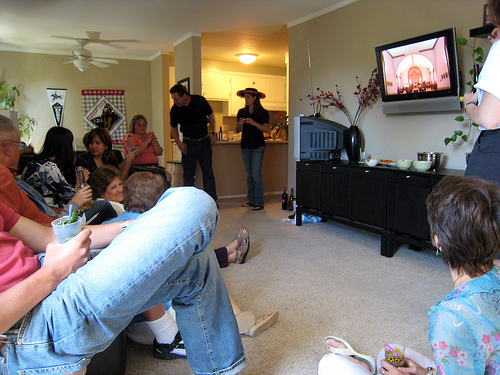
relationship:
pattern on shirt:
[438, 294, 484, 363] [418, 262, 497, 370]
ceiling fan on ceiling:
[42, 37, 119, 71] [2, 4, 159, 54]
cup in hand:
[55, 207, 89, 264] [42, 226, 91, 279]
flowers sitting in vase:
[298, 67, 384, 124] [342, 124, 362, 164]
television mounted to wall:
[373, 25, 467, 120] [283, 5, 499, 242]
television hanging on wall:
[373, 27, 466, 115] [287, 18, 367, 90]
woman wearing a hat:
[232, 87, 280, 210] [229, 82, 271, 106]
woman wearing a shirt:
[232, 87, 280, 210] [220, 103, 287, 148]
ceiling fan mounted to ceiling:
[42, 37, 119, 71] [44, 42, 120, 77]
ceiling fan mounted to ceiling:
[48, 44, 114, 72] [1, 1, 298, 29]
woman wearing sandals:
[69, 117, 129, 192] [233, 223, 251, 264]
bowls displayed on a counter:
[394, 152, 450, 189] [287, 125, 499, 274]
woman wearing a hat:
[232, 87, 280, 210] [232, 86, 266, 100]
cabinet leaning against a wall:
[295, 159, 429, 255] [287, 26, 372, 80]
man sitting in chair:
[0, 115, 63, 237] [89, 341, 126, 372]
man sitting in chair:
[2, 183, 248, 373] [89, 341, 126, 372]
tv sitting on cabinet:
[293, 113, 351, 165] [295, 159, 429, 255]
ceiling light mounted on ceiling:
[223, 37, 264, 72] [1, 2, 289, 37]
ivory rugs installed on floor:
[125, 200, 447, 373] [127, 202, 454, 374]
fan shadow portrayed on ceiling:
[53, 32, 140, 52] [1, 1, 353, 62]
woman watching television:
[302, 166, 493, 368] [375, 27, 465, 116]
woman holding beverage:
[318, 176, 500, 375] [373, 342, 424, 374]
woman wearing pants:
[211, 63, 333, 216] [240, 140, 268, 206]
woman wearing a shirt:
[211, 63, 333, 216] [236, 106, 270, 146]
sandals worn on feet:
[235, 179, 282, 269] [233, 307, 281, 337]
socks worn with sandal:
[147, 315, 177, 343] [187, 264, 301, 344]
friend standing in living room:
[233, 87, 277, 214] [29, 115, 130, 217]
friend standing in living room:
[162, 76, 219, 204] [29, 115, 130, 217]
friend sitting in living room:
[124, 114, 162, 175] [29, 115, 130, 217]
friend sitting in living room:
[66, 122, 126, 188] [29, 115, 130, 217]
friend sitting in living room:
[318, 175, 498, 374] [29, 115, 130, 217]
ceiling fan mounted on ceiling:
[42, 37, 119, 71] [0, 2, 210, 31]